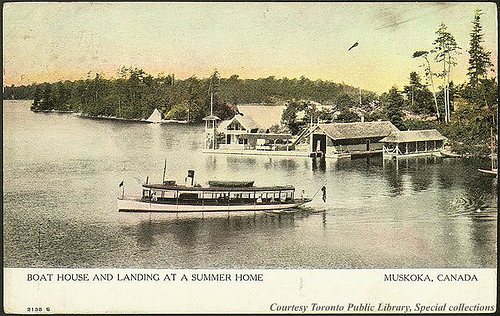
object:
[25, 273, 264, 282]
black lettering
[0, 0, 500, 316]
card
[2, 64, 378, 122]
woods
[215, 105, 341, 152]
buildings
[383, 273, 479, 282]
writing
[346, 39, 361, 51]
bird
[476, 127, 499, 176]
boat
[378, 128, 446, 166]
dock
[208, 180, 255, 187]
rowboat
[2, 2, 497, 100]
sky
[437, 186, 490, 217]
ripples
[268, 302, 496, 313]
writing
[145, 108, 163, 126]
sailboat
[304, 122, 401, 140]
roof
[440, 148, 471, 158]
boat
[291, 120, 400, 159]
boathouses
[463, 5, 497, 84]
trees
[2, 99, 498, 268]
lake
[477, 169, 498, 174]
edge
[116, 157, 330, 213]
boat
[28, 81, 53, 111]
trees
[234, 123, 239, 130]
window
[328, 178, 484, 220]
water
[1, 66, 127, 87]
light